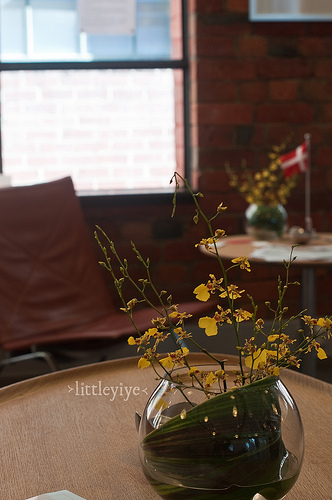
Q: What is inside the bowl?
A: Yellow flowers.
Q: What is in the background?
A: A window.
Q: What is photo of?
A: Brick wall with light streaming.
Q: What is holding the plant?
A: Round fish bowl.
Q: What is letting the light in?
A: Half open window.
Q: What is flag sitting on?
A: Small round wooden table.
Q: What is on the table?
A: A flower vase.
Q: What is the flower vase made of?
A: Glass.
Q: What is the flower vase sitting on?
A: A table.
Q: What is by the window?
A: A chair.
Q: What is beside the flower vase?
A: A flag.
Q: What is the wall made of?
A: Brick.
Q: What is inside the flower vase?
A: Water.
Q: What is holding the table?
A: A silver pole.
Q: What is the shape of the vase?
A: Round.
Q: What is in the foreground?
A: A large fish bowl vase.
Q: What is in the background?
A: Window.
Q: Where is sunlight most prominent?
A: Window.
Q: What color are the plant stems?
A: Green.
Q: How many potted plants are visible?
A: Two.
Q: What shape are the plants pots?
A: Circular.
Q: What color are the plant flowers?
A: Yellow.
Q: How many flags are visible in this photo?
A: One.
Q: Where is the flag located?
A: The farther table.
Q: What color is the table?
A: Brown.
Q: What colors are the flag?
A: Red and white.